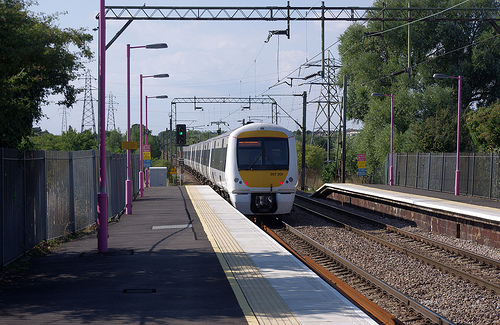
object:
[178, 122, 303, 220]
train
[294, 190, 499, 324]
tracks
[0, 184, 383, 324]
platform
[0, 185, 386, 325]
ground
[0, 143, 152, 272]
fencing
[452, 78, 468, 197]
pole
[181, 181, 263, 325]
line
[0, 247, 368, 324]
shadow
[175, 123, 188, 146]
sign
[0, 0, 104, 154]
tree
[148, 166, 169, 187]
structure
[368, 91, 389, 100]
light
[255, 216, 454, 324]
rail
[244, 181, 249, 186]
light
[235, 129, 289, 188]
accents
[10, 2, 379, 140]
sky